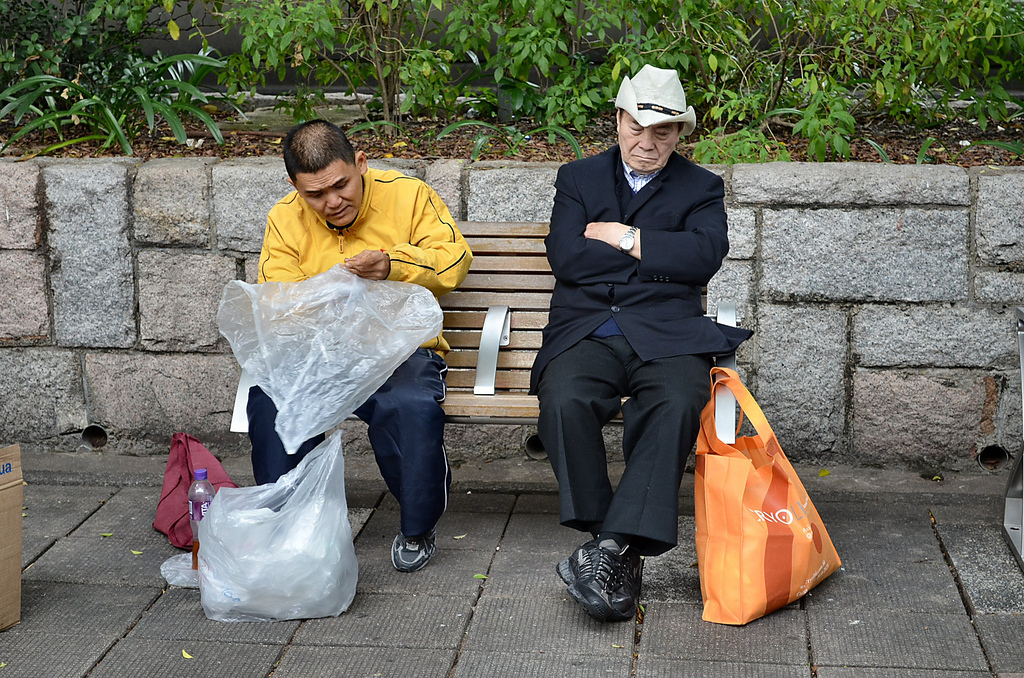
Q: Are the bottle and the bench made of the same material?
A: No, the bottle is made of plastic and the bench is made of wood.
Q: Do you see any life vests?
A: No, there are no life vests.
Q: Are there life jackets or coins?
A: No, there are no life jackets or coins.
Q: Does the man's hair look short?
A: Yes, the hair is short.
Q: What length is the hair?
A: The hair is short.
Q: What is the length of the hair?
A: The hair is short.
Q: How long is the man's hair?
A: The hair is short.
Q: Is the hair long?
A: No, the hair is short.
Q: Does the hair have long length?
A: No, the hair is short.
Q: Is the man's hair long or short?
A: The hair is short.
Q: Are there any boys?
A: No, there are no boys.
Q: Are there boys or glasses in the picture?
A: No, there are no boys or glasses.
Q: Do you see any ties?
A: No, there are no ties.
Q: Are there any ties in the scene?
A: No, there are no ties.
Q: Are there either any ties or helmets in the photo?
A: No, there are no ties or helmets.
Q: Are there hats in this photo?
A: Yes, there is a hat.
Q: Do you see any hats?
A: Yes, there is a hat.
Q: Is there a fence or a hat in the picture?
A: Yes, there is a hat.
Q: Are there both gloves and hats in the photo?
A: No, there is a hat but no gloves.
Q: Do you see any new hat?
A: Yes, there is a new hat.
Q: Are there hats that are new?
A: Yes, there is a hat that is new.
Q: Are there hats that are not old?
A: Yes, there is an new hat.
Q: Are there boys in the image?
A: No, there are no boys.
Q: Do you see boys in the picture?
A: No, there are no boys.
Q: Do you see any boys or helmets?
A: No, there are no boys or helmets.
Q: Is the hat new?
A: Yes, the hat is new.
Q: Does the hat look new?
A: Yes, the hat is new.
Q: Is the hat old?
A: No, the hat is new.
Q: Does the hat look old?
A: No, the hat is new.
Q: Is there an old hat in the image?
A: No, there is a hat but it is new.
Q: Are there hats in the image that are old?
A: No, there is a hat but it is new.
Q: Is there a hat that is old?
A: No, there is a hat but it is new.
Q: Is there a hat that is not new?
A: No, there is a hat but it is new.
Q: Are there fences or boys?
A: No, there are no boys or fences.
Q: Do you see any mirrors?
A: No, there are no mirrors.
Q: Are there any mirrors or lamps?
A: No, there are no mirrors or lamps.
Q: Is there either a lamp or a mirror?
A: No, there are no mirrors or lamps.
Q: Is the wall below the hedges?
A: Yes, the wall is below the hedges.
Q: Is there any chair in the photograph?
A: No, there are no chairs.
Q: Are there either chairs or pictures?
A: No, there are no chairs or pictures.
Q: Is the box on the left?
A: Yes, the box is on the left of the image.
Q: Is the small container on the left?
A: Yes, the box is on the left of the image.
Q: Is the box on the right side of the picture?
A: No, the box is on the left of the image.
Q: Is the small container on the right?
A: No, the box is on the left of the image.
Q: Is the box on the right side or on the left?
A: The box is on the left of the image.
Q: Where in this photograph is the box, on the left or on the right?
A: The box is on the left of the image.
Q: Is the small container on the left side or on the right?
A: The box is on the left of the image.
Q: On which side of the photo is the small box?
A: The box is on the left of the image.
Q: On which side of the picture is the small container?
A: The box is on the left of the image.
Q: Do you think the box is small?
A: Yes, the box is small.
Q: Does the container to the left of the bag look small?
A: Yes, the box is small.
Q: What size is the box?
A: The box is small.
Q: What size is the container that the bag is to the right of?
A: The box is small.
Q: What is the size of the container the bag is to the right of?
A: The box is small.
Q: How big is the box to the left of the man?
A: The box is small.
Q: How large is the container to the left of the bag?
A: The box is small.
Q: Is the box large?
A: No, the box is small.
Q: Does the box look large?
A: No, the box is small.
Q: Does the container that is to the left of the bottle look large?
A: No, the box is small.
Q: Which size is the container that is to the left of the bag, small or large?
A: The box is small.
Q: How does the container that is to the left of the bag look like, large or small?
A: The box is small.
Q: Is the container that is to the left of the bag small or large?
A: The box is small.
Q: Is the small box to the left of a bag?
A: Yes, the box is to the left of a bag.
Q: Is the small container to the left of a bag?
A: Yes, the box is to the left of a bag.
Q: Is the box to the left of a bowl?
A: No, the box is to the left of a bag.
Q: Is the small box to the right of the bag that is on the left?
A: No, the box is to the left of the bag.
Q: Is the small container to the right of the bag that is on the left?
A: No, the box is to the left of the bag.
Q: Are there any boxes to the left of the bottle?
A: Yes, there is a box to the left of the bottle.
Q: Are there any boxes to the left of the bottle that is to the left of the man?
A: Yes, there is a box to the left of the bottle.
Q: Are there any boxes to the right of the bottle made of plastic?
A: No, the box is to the left of the bottle.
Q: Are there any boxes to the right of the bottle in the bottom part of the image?
A: No, the box is to the left of the bottle.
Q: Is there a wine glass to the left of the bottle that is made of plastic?
A: No, there is a box to the left of the bottle.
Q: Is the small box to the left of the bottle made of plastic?
A: Yes, the box is to the left of the bottle.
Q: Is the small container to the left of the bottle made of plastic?
A: Yes, the box is to the left of the bottle.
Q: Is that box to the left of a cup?
A: No, the box is to the left of the bottle.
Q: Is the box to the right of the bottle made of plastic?
A: No, the box is to the left of the bottle.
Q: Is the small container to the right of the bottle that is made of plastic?
A: No, the box is to the left of the bottle.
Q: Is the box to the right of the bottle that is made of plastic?
A: No, the box is to the left of the bottle.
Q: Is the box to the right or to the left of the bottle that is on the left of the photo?
A: The box is to the left of the bottle.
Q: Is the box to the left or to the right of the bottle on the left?
A: The box is to the left of the bottle.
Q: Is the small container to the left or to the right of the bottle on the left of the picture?
A: The box is to the left of the bottle.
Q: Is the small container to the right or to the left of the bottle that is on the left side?
A: The box is to the left of the bottle.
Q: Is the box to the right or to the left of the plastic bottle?
A: The box is to the left of the bottle.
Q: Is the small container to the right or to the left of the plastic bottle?
A: The box is to the left of the bottle.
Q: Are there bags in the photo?
A: Yes, there is a bag.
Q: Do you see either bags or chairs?
A: Yes, there is a bag.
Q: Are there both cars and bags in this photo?
A: No, there is a bag but no cars.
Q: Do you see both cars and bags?
A: No, there is a bag but no cars.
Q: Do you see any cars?
A: No, there are no cars.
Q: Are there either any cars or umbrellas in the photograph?
A: No, there are no cars or umbrellas.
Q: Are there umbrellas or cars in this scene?
A: No, there are no cars or umbrellas.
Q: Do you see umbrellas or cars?
A: No, there are no cars or umbrellas.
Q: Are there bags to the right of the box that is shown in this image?
A: Yes, there is a bag to the right of the box.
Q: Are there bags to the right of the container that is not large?
A: Yes, there is a bag to the right of the box.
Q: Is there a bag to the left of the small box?
A: No, the bag is to the right of the box.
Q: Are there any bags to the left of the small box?
A: No, the bag is to the right of the box.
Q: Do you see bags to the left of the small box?
A: No, the bag is to the right of the box.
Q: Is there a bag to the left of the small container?
A: No, the bag is to the right of the box.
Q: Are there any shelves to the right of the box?
A: No, there is a bag to the right of the box.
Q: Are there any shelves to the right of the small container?
A: No, there is a bag to the right of the box.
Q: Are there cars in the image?
A: No, there are no cars.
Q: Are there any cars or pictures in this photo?
A: No, there are no cars or pictures.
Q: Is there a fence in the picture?
A: No, there are no fences.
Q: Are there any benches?
A: Yes, there is a bench.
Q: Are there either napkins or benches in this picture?
A: Yes, there is a bench.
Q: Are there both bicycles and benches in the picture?
A: No, there is a bench but no bikes.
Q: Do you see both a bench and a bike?
A: No, there is a bench but no bikes.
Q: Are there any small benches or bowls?
A: Yes, there is a small bench.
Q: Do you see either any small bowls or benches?
A: Yes, there is a small bench.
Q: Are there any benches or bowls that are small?
A: Yes, the bench is small.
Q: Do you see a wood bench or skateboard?
A: Yes, there is a wood bench.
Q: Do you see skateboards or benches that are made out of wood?
A: Yes, the bench is made of wood.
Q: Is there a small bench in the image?
A: Yes, there is a small bench.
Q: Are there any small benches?
A: Yes, there is a small bench.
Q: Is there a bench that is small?
A: Yes, there is a bench that is small.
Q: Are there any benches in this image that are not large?
A: Yes, there is a small bench.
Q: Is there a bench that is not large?
A: Yes, there is a small bench.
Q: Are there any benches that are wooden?
A: Yes, there is a wood bench.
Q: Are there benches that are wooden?
A: Yes, there is a bench that is wooden.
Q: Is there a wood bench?
A: Yes, there is a bench that is made of wood.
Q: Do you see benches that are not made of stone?
A: Yes, there is a bench that is made of wood.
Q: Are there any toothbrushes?
A: No, there are no toothbrushes.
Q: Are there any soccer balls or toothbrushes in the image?
A: No, there are no toothbrushes or soccer balls.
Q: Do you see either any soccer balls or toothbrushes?
A: No, there are no toothbrushes or soccer balls.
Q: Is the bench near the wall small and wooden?
A: Yes, the bench is small and wooden.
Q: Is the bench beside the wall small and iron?
A: No, the bench is small but wooden.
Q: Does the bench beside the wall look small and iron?
A: No, the bench is small but wooden.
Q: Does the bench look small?
A: Yes, the bench is small.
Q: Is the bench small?
A: Yes, the bench is small.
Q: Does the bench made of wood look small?
A: Yes, the bench is small.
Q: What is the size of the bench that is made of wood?
A: The bench is small.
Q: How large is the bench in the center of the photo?
A: The bench is small.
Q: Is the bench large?
A: No, the bench is small.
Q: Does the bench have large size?
A: No, the bench is small.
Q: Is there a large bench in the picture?
A: No, there is a bench but it is small.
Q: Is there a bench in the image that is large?
A: No, there is a bench but it is small.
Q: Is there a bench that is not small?
A: No, there is a bench but it is small.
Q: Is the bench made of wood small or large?
A: The bench is small.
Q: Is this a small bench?
A: Yes, this is a small bench.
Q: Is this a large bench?
A: No, this is a small bench.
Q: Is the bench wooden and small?
A: Yes, the bench is wooden and small.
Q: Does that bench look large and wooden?
A: No, the bench is wooden but small.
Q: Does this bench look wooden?
A: Yes, the bench is wooden.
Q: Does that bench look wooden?
A: Yes, the bench is wooden.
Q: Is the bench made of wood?
A: Yes, the bench is made of wood.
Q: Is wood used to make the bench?
A: Yes, the bench is made of wood.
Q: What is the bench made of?
A: The bench is made of wood.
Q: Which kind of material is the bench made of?
A: The bench is made of wood.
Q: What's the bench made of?
A: The bench is made of wood.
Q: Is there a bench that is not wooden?
A: No, there is a bench but it is wooden.